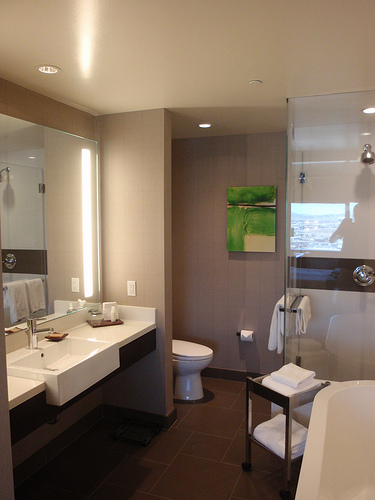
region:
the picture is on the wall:
[212, 176, 278, 257]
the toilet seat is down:
[137, 312, 223, 415]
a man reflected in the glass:
[285, 177, 373, 285]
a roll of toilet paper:
[228, 318, 261, 350]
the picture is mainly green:
[210, 175, 282, 260]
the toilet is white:
[163, 321, 209, 414]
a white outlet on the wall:
[110, 268, 144, 304]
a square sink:
[15, 335, 119, 375]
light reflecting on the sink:
[58, 325, 124, 366]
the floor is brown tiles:
[92, 419, 225, 490]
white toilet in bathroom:
[162, 327, 226, 406]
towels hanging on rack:
[263, 283, 296, 356]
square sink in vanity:
[23, 328, 110, 390]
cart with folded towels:
[243, 365, 320, 468]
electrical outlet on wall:
[116, 277, 139, 307]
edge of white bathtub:
[295, 396, 341, 490]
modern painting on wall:
[219, 180, 282, 259]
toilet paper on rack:
[232, 323, 260, 347]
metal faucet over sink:
[21, 310, 64, 352]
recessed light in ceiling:
[192, 115, 223, 136]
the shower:
[269, 91, 373, 380]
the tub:
[287, 369, 373, 498]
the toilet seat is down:
[171, 329, 217, 401]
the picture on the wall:
[224, 180, 279, 258]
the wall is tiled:
[174, 167, 225, 312]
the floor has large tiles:
[127, 436, 208, 493]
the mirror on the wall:
[2, 113, 101, 317]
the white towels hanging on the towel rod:
[7, 278, 57, 316]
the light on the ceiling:
[189, 115, 219, 134]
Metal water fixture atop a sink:
[11, 307, 60, 354]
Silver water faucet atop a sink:
[14, 308, 59, 355]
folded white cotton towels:
[248, 353, 319, 400]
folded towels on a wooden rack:
[234, 352, 320, 476]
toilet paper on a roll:
[226, 320, 256, 346]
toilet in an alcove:
[171, 326, 212, 402]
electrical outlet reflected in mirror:
[51, 255, 150, 302]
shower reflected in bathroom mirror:
[0, 126, 61, 316]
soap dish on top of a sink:
[45, 321, 68, 343]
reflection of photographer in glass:
[322, 188, 370, 253]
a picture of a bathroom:
[11, 184, 359, 434]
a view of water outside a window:
[254, 102, 371, 317]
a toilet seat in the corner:
[139, 264, 223, 419]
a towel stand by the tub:
[225, 348, 347, 486]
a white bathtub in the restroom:
[288, 360, 374, 498]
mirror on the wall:
[2, 113, 110, 319]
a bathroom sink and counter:
[3, 298, 154, 403]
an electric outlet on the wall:
[57, 250, 149, 318]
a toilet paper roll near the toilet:
[173, 296, 259, 419]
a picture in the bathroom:
[207, 169, 295, 315]